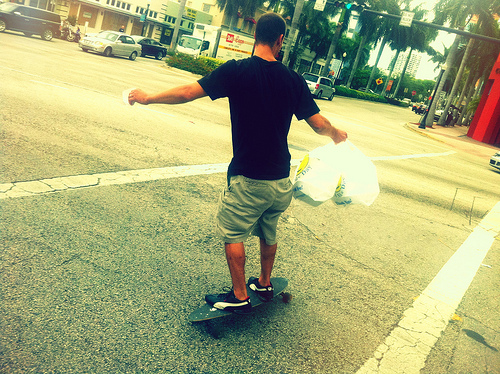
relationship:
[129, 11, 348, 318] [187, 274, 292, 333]
he on skate board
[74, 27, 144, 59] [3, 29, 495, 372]
car on street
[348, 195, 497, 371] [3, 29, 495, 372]
lines on street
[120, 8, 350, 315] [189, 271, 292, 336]
he on skateboard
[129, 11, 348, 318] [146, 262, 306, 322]
he on skateboard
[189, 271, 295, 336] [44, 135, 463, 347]
skateboard on street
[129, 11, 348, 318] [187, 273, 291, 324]
he riding skateboard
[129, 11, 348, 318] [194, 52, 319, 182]
he wearing black shirt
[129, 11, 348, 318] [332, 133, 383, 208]
he holding bag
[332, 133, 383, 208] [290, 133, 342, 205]
bag holding bag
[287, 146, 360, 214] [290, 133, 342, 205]
decal on bag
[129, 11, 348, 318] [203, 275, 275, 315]
he wearing shoes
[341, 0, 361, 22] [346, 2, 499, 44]
traffic light on pole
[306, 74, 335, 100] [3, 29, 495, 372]
car on street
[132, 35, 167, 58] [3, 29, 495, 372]
car on street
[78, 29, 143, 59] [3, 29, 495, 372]
car on street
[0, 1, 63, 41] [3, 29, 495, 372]
car on street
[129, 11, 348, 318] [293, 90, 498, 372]
he skateboarding on street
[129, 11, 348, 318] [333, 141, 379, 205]
he carrying bag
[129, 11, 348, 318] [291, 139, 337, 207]
he carrying bag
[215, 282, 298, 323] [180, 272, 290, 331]
feet on skateboard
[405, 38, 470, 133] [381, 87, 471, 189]
street light on corner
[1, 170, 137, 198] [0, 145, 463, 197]
cracks on white paint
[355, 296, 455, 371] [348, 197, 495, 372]
cracks on white paint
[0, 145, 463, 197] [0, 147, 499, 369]
white paint of crosswalk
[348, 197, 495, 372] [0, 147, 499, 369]
white paint of crosswalk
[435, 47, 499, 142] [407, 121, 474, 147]
structure on corner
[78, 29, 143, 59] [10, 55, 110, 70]
car driving down road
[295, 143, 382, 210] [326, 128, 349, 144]
bags in hand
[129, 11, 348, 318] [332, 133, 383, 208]
he is carrying bag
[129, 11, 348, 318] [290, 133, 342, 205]
he is carrying bag